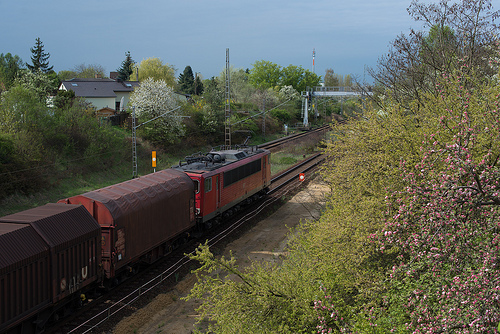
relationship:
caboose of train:
[175, 149, 273, 225] [3, 103, 273, 325]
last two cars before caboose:
[1, 168, 197, 333] [175, 149, 273, 225]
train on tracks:
[3, 103, 273, 325] [29, 120, 339, 334]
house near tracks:
[60, 78, 133, 112] [29, 120, 339, 334]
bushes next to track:
[1, 30, 357, 159] [246, 120, 339, 152]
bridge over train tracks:
[301, 87, 374, 96] [29, 120, 339, 334]